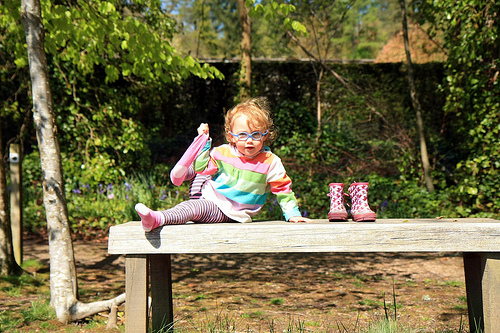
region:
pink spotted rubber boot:
[344, 177, 377, 227]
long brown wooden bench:
[97, 220, 492, 265]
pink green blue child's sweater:
[202, 144, 286, 217]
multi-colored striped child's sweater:
[196, 137, 302, 233]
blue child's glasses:
[222, 127, 277, 142]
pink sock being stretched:
[154, 116, 217, 189]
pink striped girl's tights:
[147, 190, 242, 225]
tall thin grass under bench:
[184, 287, 428, 326]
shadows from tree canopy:
[194, 259, 407, 308]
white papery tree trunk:
[13, 3, 91, 331]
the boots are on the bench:
[323, 167, 380, 225]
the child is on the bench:
[131, 69, 313, 242]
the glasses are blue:
[223, 124, 270, 144]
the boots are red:
[323, 171, 380, 227]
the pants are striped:
[171, 202, 198, 216]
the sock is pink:
[180, 137, 198, 165]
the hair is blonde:
[236, 103, 264, 131]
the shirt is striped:
[220, 160, 252, 196]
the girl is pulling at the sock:
[115, 78, 310, 237]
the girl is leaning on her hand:
[112, 75, 323, 235]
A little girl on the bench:
[92, 111, 292, 232]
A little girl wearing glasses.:
[224, 119, 274, 143]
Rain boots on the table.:
[326, 170, 385, 228]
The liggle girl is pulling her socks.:
[153, 108, 226, 194]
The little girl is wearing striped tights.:
[140, 169, 220, 224]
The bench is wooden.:
[103, 213, 494, 285]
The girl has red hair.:
[203, 94, 293, 138]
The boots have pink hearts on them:
[326, 160, 378, 220]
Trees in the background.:
[76, 17, 449, 115]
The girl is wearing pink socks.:
[131, 188, 168, 246]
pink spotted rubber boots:
[323, 176, 377, 227]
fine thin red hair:
[221, 92, 275, 134]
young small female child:
[210, 92, 295, 223]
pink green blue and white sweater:
[185, 133, 306, 235]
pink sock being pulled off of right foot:
[164, 131, 208, 191]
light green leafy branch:
[53, 9, 222, 93]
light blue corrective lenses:
[229, 128, 274, 145]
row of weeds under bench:
[196, 295, 412, 328]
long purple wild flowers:
[67, 170, 168, 210]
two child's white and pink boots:
[324, 175, 379, 231]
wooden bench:
[108, 216, 425, 321]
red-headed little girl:
[132, 101, 311, 231]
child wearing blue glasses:
[226, 123, 273, 146]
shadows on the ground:
[186, 262, 418, 309]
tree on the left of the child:
[17, 0, 114, 320]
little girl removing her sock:
[132, 92, 307, 234]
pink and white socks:
[136, 127, 212, 233]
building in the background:
[57, 55, 455, 180]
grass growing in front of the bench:
[153, 313, 477, 329]